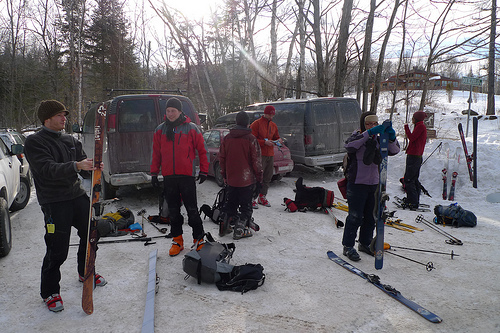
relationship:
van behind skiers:
[71, 88, 205, 202] [27, 79, 439, 311]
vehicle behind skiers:
[198, 110, 295, 187] [27, 79, 439, 311]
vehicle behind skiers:
[237, 85, 363, 176] [27, 79, 439, 311]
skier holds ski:
[28, 96, 110, 312] [79, 99, 118, 313]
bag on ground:
[176, 233, 270, 297] [11, 114, 488, 317]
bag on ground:
[284, 173, 342, 214] [11, 114, 488, 317]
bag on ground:
[432, 201, 482, 230] [11, 114, 488, 317]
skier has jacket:
[338, 112, 408, 264] [341, 115, 404, 183]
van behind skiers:
[246, 85, 369, 178] [27, 79, 439, 311]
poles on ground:
[380, 245, 464, 273] [11, 114, 488, 317]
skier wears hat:
[28, 96, 110, 312] [36, 97, 69, 123]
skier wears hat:
[145, 87, 215, 257] [164, 96, 183, 113]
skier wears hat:
[214, 107, 268, 245] [237, 105, 252, 128]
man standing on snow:
[20, 97, 114, 314] [8, 124, 487, 327]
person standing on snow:
[148, 97, 219, 263] [8, 124, 487, 327]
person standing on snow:
[211, 108, 266, 248] [8, 124, 487, 327]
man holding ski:
[20, 97, 114, 314] [79, 99, 118, 313]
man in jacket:
[143, 90, 216, 258] [149, 115, 211, 183]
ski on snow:
[79, 99, 118, 313] [8, 124, 487, 327]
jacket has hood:
[216, 124, 265, 186] [225, 124, 254, 140]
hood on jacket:
[225, 124, 254, 140] [216, 124, 265, 186]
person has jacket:
[211, 108, 266, 248] [216, 124, 265, 186]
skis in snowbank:
[458, 114, 484, 189] [390, 111, 495, 217]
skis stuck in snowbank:
[458, 114, 484, 189] [390, 111, 495, 217]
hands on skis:
[370, 120, 399, 141] [369, 120, 391, 271]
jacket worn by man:
[149, 115, 211, 183] [143, 90, 216, 258]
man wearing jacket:
[143, 90, 216, 258] [149, 115, 211, 183]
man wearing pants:
[143, 90, 216, 258] [160, 174, 201, 238]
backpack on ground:
[181, 231, 281, 297] [11, 114, 488, 317]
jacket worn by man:
[21, 126, 93, 207] [20, 93, 113, 311]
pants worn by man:
[160, 174, 201, 238] [143, 90, 216, 258]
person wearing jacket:
[148, 97, 219, 263] [149, 115, 211, 183]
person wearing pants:
[148, 97, 219, 263] [160, 174, 201, 238]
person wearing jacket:
[337, 107, 407, 260] [341, 115, 404, 183]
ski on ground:
[328, 248, 446, 323] [11, 114, 488, 317]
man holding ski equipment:
[20, 93, 113, 311] [78, 101, 113, 314]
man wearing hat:
[20, 93, 113, 311] [36, 97, 69, 123]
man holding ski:
[335, 105, 406, 262] [369, 120, 391, 271]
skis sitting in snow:
[458, 114, 484, 189] [8, 124, 487, 327]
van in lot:
[80, 88, 205, 190] [8, 127, 490, 318]